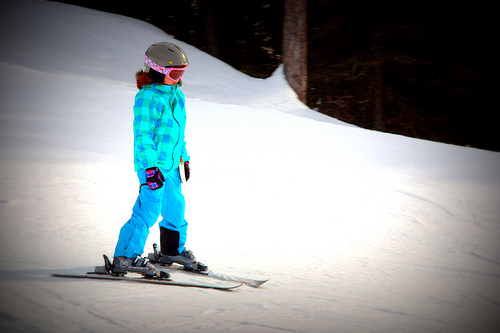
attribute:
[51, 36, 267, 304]
girl — skiing, child, standing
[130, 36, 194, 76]
helmet — grey, plastic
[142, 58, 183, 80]
goggles — pink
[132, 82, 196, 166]
jacket — blue, plaid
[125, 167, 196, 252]
pants — blue, long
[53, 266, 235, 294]
ski — grey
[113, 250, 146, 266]
boot — grey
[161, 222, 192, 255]
boot — grey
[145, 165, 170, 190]
glove — black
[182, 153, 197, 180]
glove — black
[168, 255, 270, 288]
ski — grey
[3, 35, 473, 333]
snow — white